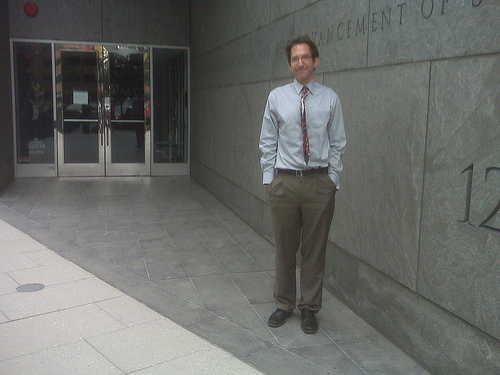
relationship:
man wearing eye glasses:
[257, 34, 348, 333] [289, 55, 313, 63]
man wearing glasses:
[257, 34, 348, 333] [287, 50, 314, 62]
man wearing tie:
[257, 34, 348, 333] [295, 84, 313, 164]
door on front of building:
[4, 31, 199, 177] [4, 6, 255, 248]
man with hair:
[257, 34, 348, 333] [290, 38, 319, 57]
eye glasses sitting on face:
[289, 55, 313, 61] [278, 32, 324, 94]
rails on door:
[64, 112, 149, 133] [54, 41, 151, 178]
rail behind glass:
[60, 116, 102, 129] [66, 58, 93, 86]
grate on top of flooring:
[13, 278, 58, 295] [0, 175, 440, 375]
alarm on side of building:
[25, 2, 38, 17] [25, 3, 496, 351]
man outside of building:
[275, 75, 372, 333] [20, 11, 249, 373]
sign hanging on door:
[51, 84, 108, 131] [36, 23, 218, 230]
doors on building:
[42, 53, 236, 195] [25, 3, 496, 351]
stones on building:
[190, 14, 295, 204] [4, 0, 498, 370]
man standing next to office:
[257, 34, 348, 333] [32, 8, 474, 277]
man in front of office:
[257, 34, 348, 333] [9, 38, 190, 176]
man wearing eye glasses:
[257, 34, 348, 333] [289, 55, 313, 61]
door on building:
[50, 40, 151, 177] [4, 0, 498, 370]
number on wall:
[457, 162, 498, 232] [188, 0, 498, 372]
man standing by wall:
[257, 34, 348, 333] [188, 0, 498, 372]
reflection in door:
[143, 87, 155, 134] [13, 35, 190, 177]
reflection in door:
[98, 102, 112, 144] [13, 35, 190, 177]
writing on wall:
[300, 0, 485, 49] [188, 0, 498, 372]